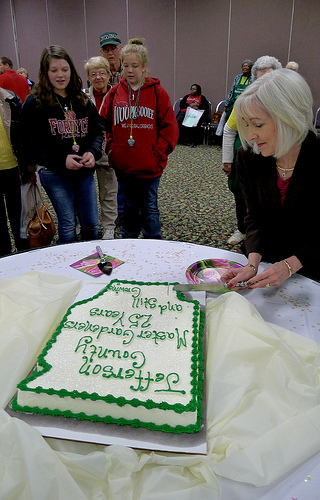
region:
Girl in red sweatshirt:
[103, 35, 182, 240]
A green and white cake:
[7, 270, 216, 451]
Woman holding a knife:
[168, 75, 314, 314]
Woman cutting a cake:
[16, 71, 314, 424]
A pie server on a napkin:
[69, 242, 123, 274]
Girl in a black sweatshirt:
[15, 49, 108, 235]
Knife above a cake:
[163, 277, 266, 293]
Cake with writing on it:
[0, 279, 220, 453]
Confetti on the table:
[114, 244, 177, 274]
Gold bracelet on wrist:
[275, 256, 296, 278]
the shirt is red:
[141, 135, 157, 146]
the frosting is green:
[120, 366, 156, 387]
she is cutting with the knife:
[216, 274, 240, 293]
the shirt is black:
[31, 118, 47, 135]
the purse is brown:
[34, 214, 45, 234]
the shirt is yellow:
[3, 144, 11, 160]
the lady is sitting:
[173, 106, 191, 122]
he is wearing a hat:
[101, 38, 117, 49]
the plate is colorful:
[200, 263, 220, 275]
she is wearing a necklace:
[276, 163, 292, 179]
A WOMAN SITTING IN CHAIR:
[178, 79, 218, 153]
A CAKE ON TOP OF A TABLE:
[35, 290, 227, 477]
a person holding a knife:
[171, 258, 267, 307]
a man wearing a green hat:
[97, 18, 123, 54]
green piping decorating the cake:
[33, 351, 206, 457]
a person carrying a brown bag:
[20, 197, 68, 239]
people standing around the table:
[25, 42, 163, 227]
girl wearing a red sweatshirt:
[93, 89, 170, 179]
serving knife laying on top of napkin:
[62, 252, 130, 280]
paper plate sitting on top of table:
[176, 256, 211, 277]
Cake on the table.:
[7, 272, 215, 436]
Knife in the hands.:
[169, 274, 255, 295]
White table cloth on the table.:
[3, 274, 318, 497]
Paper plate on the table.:
[181, 253, 251, 293]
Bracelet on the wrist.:
[276, 253, 295, 279]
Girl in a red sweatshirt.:
[99, 35, 179, 243]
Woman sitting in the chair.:
[173, 78, 212, 146]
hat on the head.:
[94, 28, 126, 68]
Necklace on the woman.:
[215, 63, 318, 184]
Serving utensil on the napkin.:
[92, 241, 114, 278]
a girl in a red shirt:
[107, 35, 167, 172]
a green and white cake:
[15, 265, 214, 436]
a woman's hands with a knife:
[220, 244, 307, 295]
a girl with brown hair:
[24, 39, 84, 119]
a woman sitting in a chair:
[169, 76, 208, 135]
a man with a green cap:
[88, 26, 122, 74]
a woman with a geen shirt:
[209, 48, 255, 108]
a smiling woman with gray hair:
[226, 64, 300, 165]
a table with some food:
[7, 237, 300, 356]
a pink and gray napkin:
[56, 235, 125, 277]